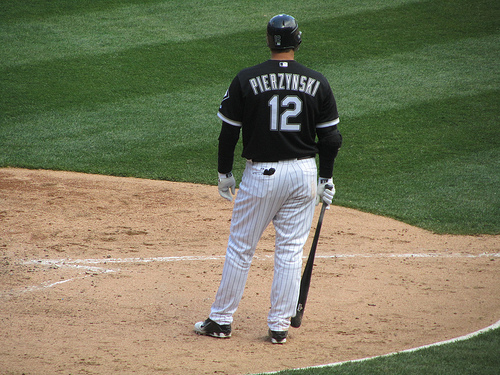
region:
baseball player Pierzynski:
[194, 11, 346, 353]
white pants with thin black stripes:
[210, 153, 338, 355]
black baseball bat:
[291, 177, 339, 328]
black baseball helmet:
[251, 3, 323, 68]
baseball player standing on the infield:
[4, 1, 488, 353]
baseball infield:
[0, 151, 495, 359]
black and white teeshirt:
[201, 50, 353, 167]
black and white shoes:
[185, 314, 305, 355]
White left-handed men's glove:
[200, 163, 241, 208]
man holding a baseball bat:
[184, 7, 351, 342]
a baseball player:
[187, 8, 361, 354]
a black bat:
[291, 177, 343, 337]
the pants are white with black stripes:
[202, 152, 333, 344]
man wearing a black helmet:
[258, 7, 310, 56]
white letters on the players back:
[242, 61, 324, 103]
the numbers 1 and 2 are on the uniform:
[260, 87, 314, 142]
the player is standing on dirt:
[2, 160, 492, 372]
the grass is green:
[0, 2, 498, 372]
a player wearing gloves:
[211, 150, 347, 216]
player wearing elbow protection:
[306, 119, 354, 176]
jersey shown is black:
[188, 7, 362, 344]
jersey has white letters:
[201, 8, 411, 368]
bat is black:
[290, 167, 340, 356]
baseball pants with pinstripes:
[217, 146, 314, 343]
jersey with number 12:
[230, 65, 325, 152]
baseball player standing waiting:
[198, 57, 384, 347]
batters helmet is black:
[212, 10, 323, 63]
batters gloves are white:
[206, 162, 242, 202]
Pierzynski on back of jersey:
[215, 73, 344, 98]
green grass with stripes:
[367, 47, 478, 213]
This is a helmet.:
[251, 5, 311, 65]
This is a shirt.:
[207, 56, 352, 171]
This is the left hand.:
[211, 166, 252, 211]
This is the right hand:
[307, 166, 347, 213]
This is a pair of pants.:
[186, 148, 318, 348]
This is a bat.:
[293, 168, 337, 327]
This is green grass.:
[104, 26, 186, 114]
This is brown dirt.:
[60, 283, 185, 333]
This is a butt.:
[242, 154, 318, 218]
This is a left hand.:
[193, 303, 239, 348]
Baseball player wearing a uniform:
[187, 8, 348, 360]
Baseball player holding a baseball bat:
[189, 11, 367, 348]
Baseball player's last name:
[246, 68, 325, 96]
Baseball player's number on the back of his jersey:
[263, 93, 305, 136]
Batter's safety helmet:
[255, 6, 317, 60]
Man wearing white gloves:
[210, 150, 359, 212]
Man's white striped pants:
[198, 155, 324, 348]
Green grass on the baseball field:
[13, 15, 211, 168]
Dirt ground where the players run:
[13, 190, 165, 347]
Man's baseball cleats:
[185, 308, 302, 352]